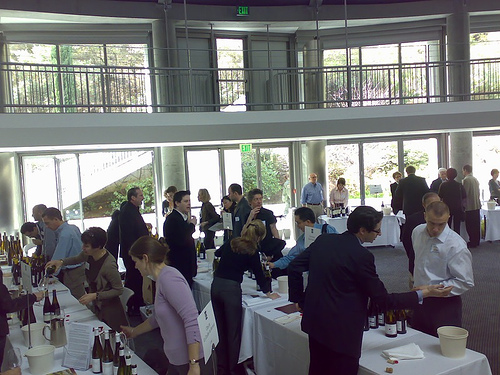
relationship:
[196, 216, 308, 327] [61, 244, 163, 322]
woman wearing sweater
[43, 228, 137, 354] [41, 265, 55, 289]
she pouring wine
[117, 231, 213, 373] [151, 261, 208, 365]
woman in sweater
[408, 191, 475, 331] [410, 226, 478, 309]
man in dress shirt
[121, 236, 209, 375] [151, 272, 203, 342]
woman wearing cardigan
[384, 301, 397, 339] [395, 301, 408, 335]
bottles next to bottles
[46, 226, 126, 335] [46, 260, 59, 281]
woman pouring wine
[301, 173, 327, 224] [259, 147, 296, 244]
man standing by door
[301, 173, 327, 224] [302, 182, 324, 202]
man in shirt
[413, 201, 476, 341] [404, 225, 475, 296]
man wearing shirt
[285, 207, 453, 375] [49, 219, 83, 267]
man wearing shirt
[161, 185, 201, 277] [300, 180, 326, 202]
man wearing shirt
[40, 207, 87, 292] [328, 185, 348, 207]
man wearing shirt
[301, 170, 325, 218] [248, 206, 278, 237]
man wearing shirt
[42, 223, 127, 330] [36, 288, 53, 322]
woman pouring wine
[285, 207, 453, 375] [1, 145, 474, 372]
man at a wine tasting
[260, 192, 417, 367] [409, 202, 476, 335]
man showing man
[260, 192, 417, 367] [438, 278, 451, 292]
man showing card